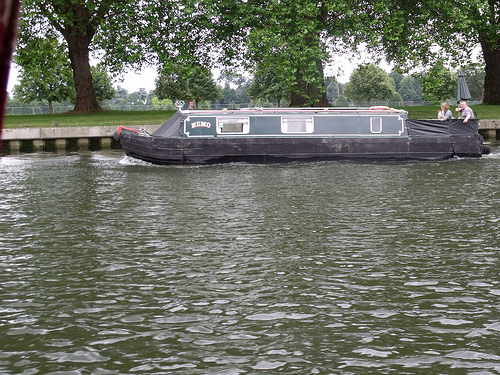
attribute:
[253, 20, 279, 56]
leaves — green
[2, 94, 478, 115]
fence — distant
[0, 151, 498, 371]
water — rippled, splashed, murky, calm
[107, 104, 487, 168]
boat — flat, long, black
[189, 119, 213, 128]
word — curved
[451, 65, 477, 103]
umbrella — closed, gray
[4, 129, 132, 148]
structure — walled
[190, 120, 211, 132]
lettering — written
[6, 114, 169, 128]
grass — green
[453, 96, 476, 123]
man — light skinned